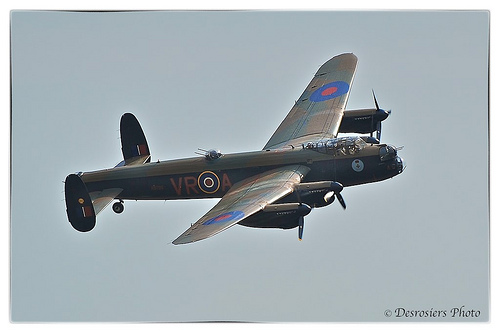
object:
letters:
[169, 170, 232, 195]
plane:
[63, 52, 403, 247]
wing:
[261, 52, 358, 148]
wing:
[171, 166, 313, 246]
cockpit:
[289, 136, 367, 157]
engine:
[238, 201, 313, 233]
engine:
[294, 180, 347, 209]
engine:
[338, 89, 391, 141]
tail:
[63, 112, 151, 232]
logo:
[197, 170, 221, 195]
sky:
[9, 9, 490, 322]